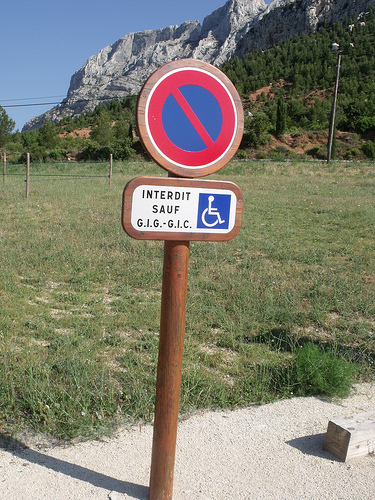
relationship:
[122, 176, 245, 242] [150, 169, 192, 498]
sign on pole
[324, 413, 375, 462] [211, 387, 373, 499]
railroad tie laying on ground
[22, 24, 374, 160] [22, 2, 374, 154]
trees are on mountain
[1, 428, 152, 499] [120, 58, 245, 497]
shadow near sign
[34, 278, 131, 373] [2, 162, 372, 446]
empty patches are in grass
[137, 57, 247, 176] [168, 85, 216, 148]
sign has diagonal line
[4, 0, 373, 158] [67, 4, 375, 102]
area has mountain tops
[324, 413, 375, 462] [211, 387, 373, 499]
railroad tie lying on ground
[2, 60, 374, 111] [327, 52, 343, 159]
power lines are on telephone pole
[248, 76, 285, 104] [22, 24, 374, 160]
area has no vegetation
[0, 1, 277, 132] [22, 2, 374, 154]
sky behind mountain